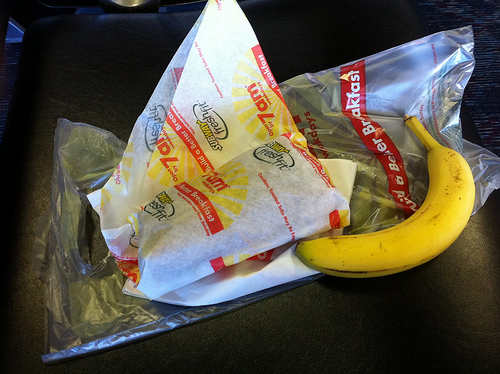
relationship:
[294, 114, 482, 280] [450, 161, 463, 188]
banana has brown spot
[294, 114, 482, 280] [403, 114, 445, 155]
banana has top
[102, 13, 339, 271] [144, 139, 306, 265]
wrapper to sandwich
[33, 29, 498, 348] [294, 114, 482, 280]
bag under banana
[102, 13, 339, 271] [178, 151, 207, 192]
wrapper has yellow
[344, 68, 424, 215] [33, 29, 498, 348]
logo on bag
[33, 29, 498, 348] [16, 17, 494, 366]
bag on table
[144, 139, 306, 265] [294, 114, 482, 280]
sandwich and banana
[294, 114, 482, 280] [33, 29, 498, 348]
banana laying on a bag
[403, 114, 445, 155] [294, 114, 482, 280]
top of banana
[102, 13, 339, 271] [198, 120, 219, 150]
wrapper from subway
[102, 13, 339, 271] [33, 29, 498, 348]
wrapper on top of bag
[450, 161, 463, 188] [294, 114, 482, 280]
spot on banana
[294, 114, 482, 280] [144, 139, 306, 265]
banana next to sandwich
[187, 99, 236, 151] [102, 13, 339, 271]
logo on wrapper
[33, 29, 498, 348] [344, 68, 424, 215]
bag has a logo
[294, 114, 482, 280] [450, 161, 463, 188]
banana has spot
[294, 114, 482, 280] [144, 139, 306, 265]
banana and a sandwich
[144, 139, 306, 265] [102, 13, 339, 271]
sandwich inside a wrapper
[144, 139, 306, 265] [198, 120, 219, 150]
sandwich from subway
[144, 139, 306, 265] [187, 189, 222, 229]
sandwich for breakfast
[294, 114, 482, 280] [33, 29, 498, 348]
banana on top of bag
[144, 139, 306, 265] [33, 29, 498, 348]
sandwich on top of bag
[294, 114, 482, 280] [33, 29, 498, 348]
banana on bag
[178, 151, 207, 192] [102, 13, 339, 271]
yellow on wrapper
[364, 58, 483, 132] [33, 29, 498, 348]
reflection of light on bag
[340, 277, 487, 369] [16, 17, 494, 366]
shadow on table